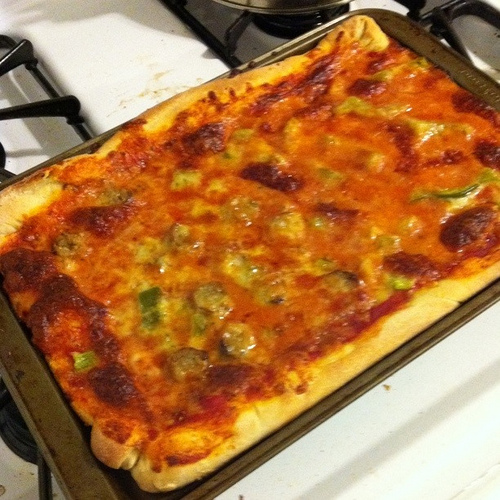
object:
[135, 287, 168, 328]
pepper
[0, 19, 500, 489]
pizza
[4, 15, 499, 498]
cheese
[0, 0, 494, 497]
pan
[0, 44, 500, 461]
cheese and peppers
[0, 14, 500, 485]
crust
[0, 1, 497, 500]
stove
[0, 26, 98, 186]
burner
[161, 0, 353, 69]
grate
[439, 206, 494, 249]
bubble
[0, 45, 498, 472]
tomato sauce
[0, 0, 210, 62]
shadow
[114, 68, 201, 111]
crumbs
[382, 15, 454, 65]
stains